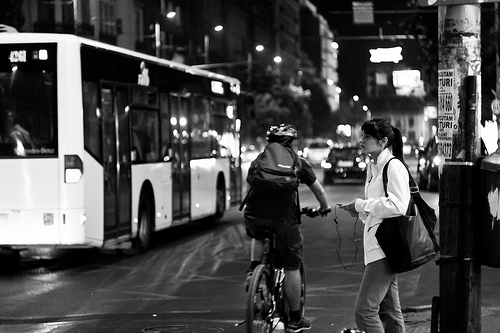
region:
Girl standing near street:
[351, 118, 432, 332]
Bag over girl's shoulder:
[379, 153, 436, 268]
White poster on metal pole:
[439, 69, 454, 158]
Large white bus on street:
[0, 34, 239, 249]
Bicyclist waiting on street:
[243, 125, 331, 331]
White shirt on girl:
[357, 152, 404, 262]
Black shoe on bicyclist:
[292, 318, 309, 330]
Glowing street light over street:
[215, 25, 224, 33]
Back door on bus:
[94, 80, 137, 234]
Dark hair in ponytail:
[367, 118, 403, 160]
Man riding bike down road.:
[239, 118, 324, 331]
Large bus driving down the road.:
[3, 20, 255, 256]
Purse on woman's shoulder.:
[372, 144, 446, 270]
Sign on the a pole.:
[428, 65, 463, 160]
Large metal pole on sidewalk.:
[417, 4, 499, 325]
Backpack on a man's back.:
[249, 135, 307, 196]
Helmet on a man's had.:
[259, 118, 296, 139]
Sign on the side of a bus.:
[205, 77, 234, 97]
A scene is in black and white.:
[1, 0, 498, 331]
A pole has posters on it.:
[436, 0, 483, 331]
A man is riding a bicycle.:
[243, 124, 330, 329]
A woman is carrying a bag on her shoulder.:
[340, 117, 440, 331]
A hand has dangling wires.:
[334, 200, 359, 266]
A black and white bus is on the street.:
[0, 18, 243, 255]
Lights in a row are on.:
[165, 9, 369, 115]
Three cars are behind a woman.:
[304, 136, 489, 188]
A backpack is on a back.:
[247, 142, 304, 192]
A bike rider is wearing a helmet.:
[243, 125, 330, 330]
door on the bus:
[98, 81, 130, 233]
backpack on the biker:
[242, 145, 307, 188]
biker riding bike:
[240, 122, 332, 332]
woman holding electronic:
[332, 118, 437, 328]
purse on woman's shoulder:
[377, 154, 437, 271]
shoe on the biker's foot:
[280, 316, 312, 331]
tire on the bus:
[135, 187, 163, 254]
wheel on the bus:
[212, 178, 234, 217]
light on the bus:
[63, 155, 83, 181]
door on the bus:
[166, 93, 202, 223]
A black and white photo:
[1, 0, 496, 331]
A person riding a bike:
[233, 120, 331, 328]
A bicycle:
[230, 203, 332, 331]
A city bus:
[1, 22, 246, 268]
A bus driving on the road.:
[0, 22, 284, 309]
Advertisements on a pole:
[431, 65, 461, 164]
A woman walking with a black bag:
[332, 115, 441, 331]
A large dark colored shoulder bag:
[376, 147, 440, 275]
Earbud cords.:
[331, 143, 370, 273]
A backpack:
[248, 134, 305, 194]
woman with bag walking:
[340, 117, 442, 332]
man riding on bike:
[233, 123, 333, 332]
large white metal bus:
[0, 29, 239, 256]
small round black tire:
[131, 205, 156, 250]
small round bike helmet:
[265, 121, 297, 139]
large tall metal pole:
[436, 3, 485, 332]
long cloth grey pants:
[356, 259, 410, 331]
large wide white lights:
[368, 44, 406, 63]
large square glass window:
[0, 41, 59, 159]